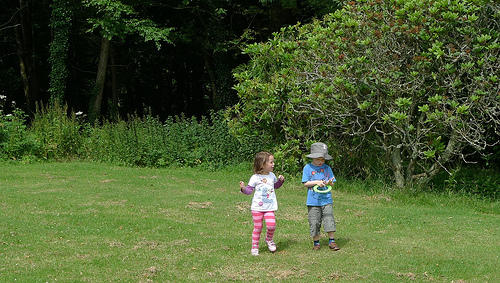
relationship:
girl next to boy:
[238, 150, 285, 256] [302, 142, 342, 250]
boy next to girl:
[302, 142, 342, 250] [238, 150, 285, 256]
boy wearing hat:
[302, 142, 342, 250] [304, 142, 333, 160]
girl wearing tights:
[238, 150, 285, 256] [251, 209, 277, 249]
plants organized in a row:
[126, 106, 163, 168] [0, 100, 259, 167]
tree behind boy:
[228, 0, 500, 193] [302, 142, 342, 250]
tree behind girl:
[228, 0, 500, 193] [238, 150, 285, 256]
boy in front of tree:
[302, 142, 342, 250] [228, 0, 500, 193]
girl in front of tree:
[238, 150, 285, 256] [228, 0, 500, 193]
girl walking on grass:
[238, 150, 285, 256] [2, 164, 500, 276]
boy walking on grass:
[302, 142, 342, 250] [2, 164, 500, 276]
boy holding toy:
[302, 142, 342, 250] [313, 183, 333, 194]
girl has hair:
[238, 150, 285, 256] [252, 150, 274, 174]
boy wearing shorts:
[302, 142, 342, 250] [307, 205, 335, 237]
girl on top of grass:
[238, 150, 285, 256] [2, 164, 500, 276]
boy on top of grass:
[302, 142, 342, 250] [2, 164, 500, 276]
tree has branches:
[228, 0, 500, 193] [350, 112, 435, 154]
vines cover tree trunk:
[50, 8, 73, 18] [49, 1, 69, 113]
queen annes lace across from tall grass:
[0, 94, 26, 125] [399, 184, 499, 207]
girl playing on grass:
[238, 150, 285, 256] [2, 164, 500, 276]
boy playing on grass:
[302, 142, 342, 250] [2, 164, 500, 276]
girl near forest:
[238, 150, 285, 256] [1, 1, 243, 128]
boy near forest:
[302, 142, 342, 250] [1, 1, 243, 128]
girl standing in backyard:
[238, 150, 285, 256] [0, 1, 498, 282]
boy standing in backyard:
[302, 142, 342, 250] [0, 1, 498, 282]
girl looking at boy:
[238, 150, 285, 256] [302, 142, 342, 250]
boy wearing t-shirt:
[302, 142, 342, 250] [302, 163, 338, 207]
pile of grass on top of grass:
[186, 199, 214, 211] [2, 164, 500, 276]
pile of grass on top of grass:
[234, 199, 251, 214] [2, 164, 500, 276]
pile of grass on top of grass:
[146, 265, 160, 277] [2, 164, 500, 276]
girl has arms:
[238, 150, 285, 256] [238, 175, 256, 195]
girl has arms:
[238, 150, 285, 256] [273, 173, 285, 190]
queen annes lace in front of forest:
[0, 94, 26, 125] [1, 1, 243, 128]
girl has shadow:
[238, 150, 285, 256] [258, 238, 299, 253]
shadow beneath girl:
[258, 238, 299, 253] [238, 150, 285, 256]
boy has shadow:
[302, 142, 342, 250] [315, 237, 352, 251]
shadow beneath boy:
[315, 237, 352, 251] [302, 142, 342, 250]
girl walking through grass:
[238, 150, 285, 256] [2, 164, 500, 276]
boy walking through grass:
[302, 142, 342, 250] [2, 164, 500, 276]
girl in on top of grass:
[238, 150, 285, 256] [2, 164, 500, 276]